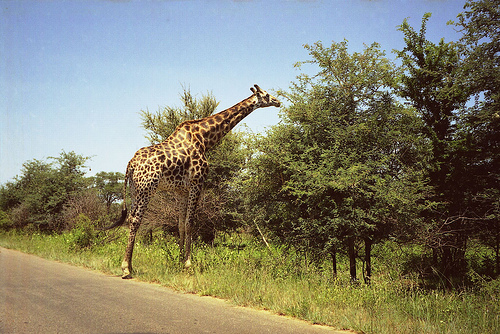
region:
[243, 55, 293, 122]
the head of a giraffe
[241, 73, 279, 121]
the ear of a giraffe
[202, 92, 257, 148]
the neck of a giraffe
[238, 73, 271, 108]
the horns of a giraffe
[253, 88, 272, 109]
the eye of a giraffe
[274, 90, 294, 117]
the mouth of a giraffe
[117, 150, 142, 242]
the tail of a giraffe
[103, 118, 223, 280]
the body of a giraffe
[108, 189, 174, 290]
the back legs of a giraffe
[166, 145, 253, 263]
the front legs of a giraffe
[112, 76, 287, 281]
A giraffe eating leaves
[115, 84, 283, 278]
a tall brown and tan giraffe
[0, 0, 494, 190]
a blue clear sky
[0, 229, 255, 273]
flowers beside the road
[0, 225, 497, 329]
tall grass beside the road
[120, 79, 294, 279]
a giraffe eating leaves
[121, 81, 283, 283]
the giraffe is standing still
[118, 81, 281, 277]
the giraffe has a long neck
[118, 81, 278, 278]
the giraffe has brown spots all over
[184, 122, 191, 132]
brown spot giraffe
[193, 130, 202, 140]
brown spot giraffe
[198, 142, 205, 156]
brown spot giraffe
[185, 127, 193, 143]
brown spot giraffe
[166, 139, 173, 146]
brown spot giraffe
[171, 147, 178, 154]
brown spot giraffe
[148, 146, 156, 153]
brown spot giraffe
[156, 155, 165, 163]
brown spot giraffe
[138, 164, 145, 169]
brown spot giraffe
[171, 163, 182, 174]
brown spot giraffe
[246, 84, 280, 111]
head belongs to giraffe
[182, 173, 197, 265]
leg belongs to giraffe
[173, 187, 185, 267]
leg belongs to giraffe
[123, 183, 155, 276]
leg belongs to giraffe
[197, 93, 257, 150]
neck belongs to giraffe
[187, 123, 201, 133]
spot belongs to giraffe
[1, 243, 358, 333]
street behind giraffe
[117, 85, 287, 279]
giraffe next to street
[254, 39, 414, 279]
tree in front of giraffe